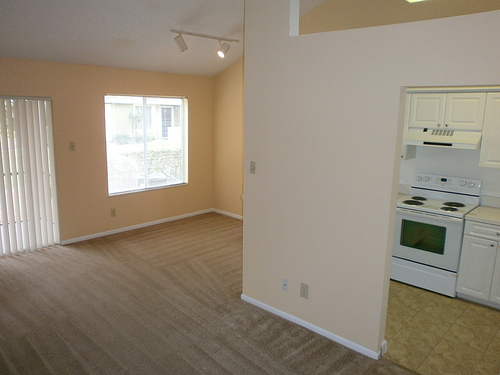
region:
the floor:
[110, 225, 167, 327]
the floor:
[47, 232, 145, 356]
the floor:
[79, 250, 196, 374]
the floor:
[120, 316, 188, 367]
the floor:
[77, 247, 139, 334]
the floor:
[96, 280, 143, 332]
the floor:
[107, 291, 158, 361]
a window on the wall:
[97, 85, 195, 202]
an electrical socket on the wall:
[295, 278, 315, 305]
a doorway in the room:
[0, 89, 64, 262]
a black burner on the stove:
[440, 194, 467, 210]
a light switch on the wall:
[245, 156, 259, 177]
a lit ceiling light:
[207, 37, 234, 63]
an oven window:
[396, 216, 459, 256]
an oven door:
[391, 202, 465, 272]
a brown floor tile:
[393, 317, 445, 358]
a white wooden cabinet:
[438, 87, 487, 129]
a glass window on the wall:
[98, 87, 198, 199]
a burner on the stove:
[439, 196, 466, 208]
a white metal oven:
[388, 170, 488, 300]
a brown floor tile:
[408, 309, 457, 342]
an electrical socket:
[296, 275, 312, 302]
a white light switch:
[245, 156, 261, 183]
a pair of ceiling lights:
[168, 20, 250, 72]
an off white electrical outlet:
[293, 280, 314, 303]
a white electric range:
[391, 164, 486, 219]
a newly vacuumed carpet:
[16, 203, 345, 366]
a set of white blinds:
[3, 101, 72, 256]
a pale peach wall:
[236, 103, 413, 361]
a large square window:
[98, 59, 204, 206]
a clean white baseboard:
[230, 287, 383, 361]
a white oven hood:
[401, 110, 486, 173]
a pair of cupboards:
[402, 85, 492, 134]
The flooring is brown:
[35, 219, 305, 354]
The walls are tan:
[251, 62, 390, 335]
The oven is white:
[396, 162, 468, 304]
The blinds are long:
[6, 91, 93, 261]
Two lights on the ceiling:
[158, 21, 253, 71]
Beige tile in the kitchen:
[389, 265, 486, 367]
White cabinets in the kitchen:
[426, 106, 494, 298]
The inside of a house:
[69, 12, 452, 358]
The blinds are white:
[4, 94, 78, 250]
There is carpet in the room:
[25, 198, 338, 360]